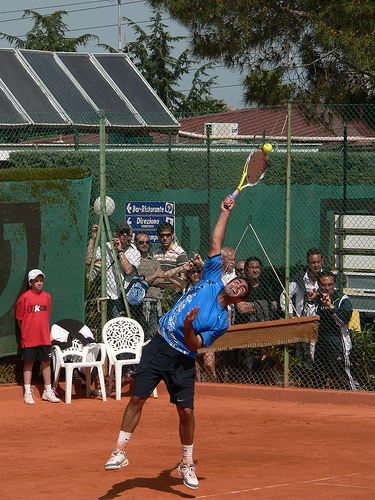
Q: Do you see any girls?
A: No, there are no girls.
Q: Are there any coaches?
A: No, there are no coaches.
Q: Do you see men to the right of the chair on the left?
A: Yes, there is a man to the right of the chair.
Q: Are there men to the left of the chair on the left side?
A: No, the man is to the right of the chair.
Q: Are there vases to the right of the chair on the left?
A: No, there is a man to the right of the chair.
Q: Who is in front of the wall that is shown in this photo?
A: The man is in front of the wall.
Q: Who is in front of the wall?
A: The man is in front of the wall.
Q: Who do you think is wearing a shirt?
A: The man is wearing a shirt.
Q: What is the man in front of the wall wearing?
A: The man is wearing a shirt.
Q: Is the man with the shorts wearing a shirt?
A: Yes, the man is wearing a shirt.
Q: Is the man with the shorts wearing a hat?
A: No, the man is wearing a shirt.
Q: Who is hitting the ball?
A: The man is hitting the ball.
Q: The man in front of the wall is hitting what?
A: The man is hitting the ball.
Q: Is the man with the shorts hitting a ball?
A: Yes, the man is hitting a ball.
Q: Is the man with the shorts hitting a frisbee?
A: No, the man is hitting a ball.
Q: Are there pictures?
A: No, there are no pictures.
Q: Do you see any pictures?
A: No, there are no pictures.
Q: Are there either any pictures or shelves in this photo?
A: No, there are no pictures or shelves.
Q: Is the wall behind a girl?
A: No, the wall is behind a man.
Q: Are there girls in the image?
A: No, there are no girls.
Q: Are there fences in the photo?
A: Yes, there is a fence.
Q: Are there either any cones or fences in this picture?
A: Yes, there is a fence.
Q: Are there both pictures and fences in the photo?
A: No, there is a fence but no pictures.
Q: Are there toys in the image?
A: No, there are no toys.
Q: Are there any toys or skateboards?
A: No, there are no toys or skateboards.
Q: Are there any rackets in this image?
A: Yes, there is a racket.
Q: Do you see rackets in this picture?
A: Yes, there is a racket.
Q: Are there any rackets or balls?
A: Yes, there is a racket.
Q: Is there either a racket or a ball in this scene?
A: Yes, there is a racket.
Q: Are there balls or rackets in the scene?
A: Yes, there is a racket.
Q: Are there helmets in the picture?
A: No, there are no helmets.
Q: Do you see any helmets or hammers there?
A: No, there are no helmets or hammers.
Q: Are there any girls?
A: No, there are no girls.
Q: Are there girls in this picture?
A: No, there are no girls.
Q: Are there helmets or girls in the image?
A: No, there are no girls or helmets.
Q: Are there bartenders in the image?
A: No, there are no bartenders.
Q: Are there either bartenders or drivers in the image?
A: No, there are no bartenders or drivers.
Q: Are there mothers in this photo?
A: No, there are no mothers.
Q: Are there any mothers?
A: No, there are no mothers.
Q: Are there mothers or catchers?
A: No, there are no mothers or catchers.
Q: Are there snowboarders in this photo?
A: No, there are no snowboarders.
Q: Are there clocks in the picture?
A: No, there are no clocks.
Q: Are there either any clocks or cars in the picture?
A: No, there are no clocks or cars.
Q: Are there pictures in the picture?
A: No, there are no pictures.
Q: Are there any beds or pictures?
A: No, there are no pictures or beds.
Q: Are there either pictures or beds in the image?
A: No, there are no pictures or beds.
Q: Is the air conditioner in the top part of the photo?
A: Yes, the air conditioner is in the top of the image.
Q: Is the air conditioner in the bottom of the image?
A: No, the air conditioner is in the top of the image.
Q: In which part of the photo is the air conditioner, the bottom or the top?
A: The air conditioner is in the top of the image.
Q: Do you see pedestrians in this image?
A: No, there are no pedestrians.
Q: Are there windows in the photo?
A: Yes, there is a window.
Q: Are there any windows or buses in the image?
A: Yes, there is a window.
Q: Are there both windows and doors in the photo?
A: No, there is a window but no doors.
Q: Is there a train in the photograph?
A: No, there are no trains.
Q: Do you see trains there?
A: No, there are no trains.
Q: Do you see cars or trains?
A: No, there are no trains or cars.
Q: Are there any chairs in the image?
A: Yes, there is a chair.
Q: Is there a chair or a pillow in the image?
A: Yes, there is a chair.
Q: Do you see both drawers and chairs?
A: No, there is a chair but no drawers.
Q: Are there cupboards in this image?
A: No, there are no cupboards.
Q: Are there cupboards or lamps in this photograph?
A: No, there are no cupboards or lamps.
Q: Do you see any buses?
A: No, there are no buses.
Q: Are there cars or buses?
A: No, there are no buses or cars.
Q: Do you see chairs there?
A: Yes, there is a chair.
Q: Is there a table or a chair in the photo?
A: Yes, there is a chair.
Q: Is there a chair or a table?
A: Yes, there is a chair.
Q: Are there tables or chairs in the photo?
A: Yes, there is a chair.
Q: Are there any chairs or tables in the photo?
A: Yes, there is a chair.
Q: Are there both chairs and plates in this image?
A: No, there is a chair but no plates.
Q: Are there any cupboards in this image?
A: No, there are no cupboards.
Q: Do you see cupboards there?
A: No, there are no cupboards.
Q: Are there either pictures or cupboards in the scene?
A: No, there are no cupboards or pictures.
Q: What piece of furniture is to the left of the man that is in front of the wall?
A: The piece of furniture is a chair.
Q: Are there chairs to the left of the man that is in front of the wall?
A: Yes, there is a chair to the left of the man.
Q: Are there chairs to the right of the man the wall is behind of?
A: No, the chair is to the left of the man.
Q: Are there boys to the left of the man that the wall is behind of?
A: No, there is a chair to the left of the man.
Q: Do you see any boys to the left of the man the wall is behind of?
A: No, there is a chair to the left of the man.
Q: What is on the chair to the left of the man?
A: The jacket is on the chair.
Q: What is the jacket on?
A: The jacket is on the chair.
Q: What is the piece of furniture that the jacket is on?
A: The piece of furniture is a chair.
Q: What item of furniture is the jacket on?
A: The jacket is on the chair.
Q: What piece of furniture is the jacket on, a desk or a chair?
A: The jacket is on a chair.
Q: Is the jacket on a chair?
A: Yes, the jacket is on a chair.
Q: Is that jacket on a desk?
A: No, the jacket is on a chair.